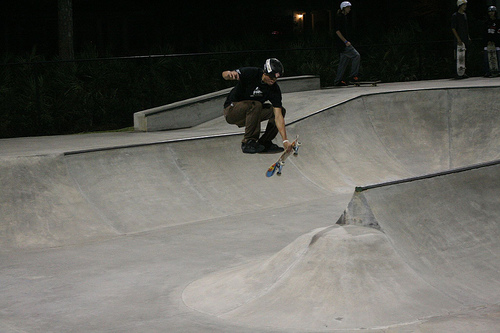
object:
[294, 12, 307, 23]
light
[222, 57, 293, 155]
man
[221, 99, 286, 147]
pants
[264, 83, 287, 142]
arm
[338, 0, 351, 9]
helmet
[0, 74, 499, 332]
skate park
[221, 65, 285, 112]
shirt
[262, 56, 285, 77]
helmet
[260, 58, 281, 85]
head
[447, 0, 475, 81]
person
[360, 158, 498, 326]
ramp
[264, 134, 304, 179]
skate board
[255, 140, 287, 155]
shoes